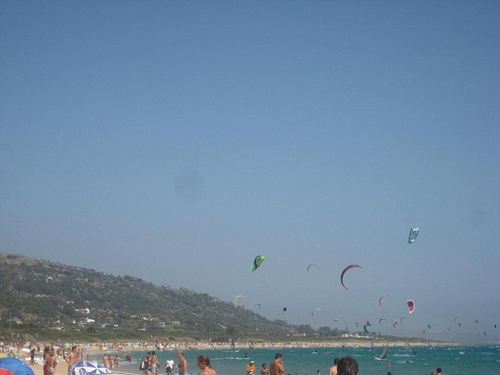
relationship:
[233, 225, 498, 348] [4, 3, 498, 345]
parasails are in air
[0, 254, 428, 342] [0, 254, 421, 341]
trees are on hill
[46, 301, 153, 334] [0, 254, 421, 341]
buildings sitting on hill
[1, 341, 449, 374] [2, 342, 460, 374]
crowd on beach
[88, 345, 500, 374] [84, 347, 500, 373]
ocean has water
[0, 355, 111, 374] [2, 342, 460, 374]
umbrellas are on beach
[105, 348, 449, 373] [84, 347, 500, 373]
people swimming in water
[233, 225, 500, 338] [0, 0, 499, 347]
kites in sky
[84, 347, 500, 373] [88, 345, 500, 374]
water in ocean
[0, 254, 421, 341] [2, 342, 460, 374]
hill by beach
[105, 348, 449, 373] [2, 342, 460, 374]
people at beach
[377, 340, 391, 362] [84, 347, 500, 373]
sail in water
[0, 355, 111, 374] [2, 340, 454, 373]
umbrellas in sand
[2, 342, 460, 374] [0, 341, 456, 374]
beach has shore line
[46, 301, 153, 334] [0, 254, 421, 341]
buildings on hill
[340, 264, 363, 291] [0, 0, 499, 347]
kite in sky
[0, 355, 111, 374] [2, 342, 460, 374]
umbrellas set up on beach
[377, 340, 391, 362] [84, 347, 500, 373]
sail on water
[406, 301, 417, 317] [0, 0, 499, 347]
kite in sky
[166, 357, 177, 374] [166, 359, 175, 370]
person wearing shirt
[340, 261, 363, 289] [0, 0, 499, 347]
kite flying in sky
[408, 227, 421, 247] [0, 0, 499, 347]
kite flying in sky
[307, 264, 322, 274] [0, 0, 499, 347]
kite flying in sky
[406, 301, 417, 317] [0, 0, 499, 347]
kite flying in sky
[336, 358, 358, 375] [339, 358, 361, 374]
person has hair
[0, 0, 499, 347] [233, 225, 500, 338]
sky has kites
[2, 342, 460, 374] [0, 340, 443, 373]
beach has people